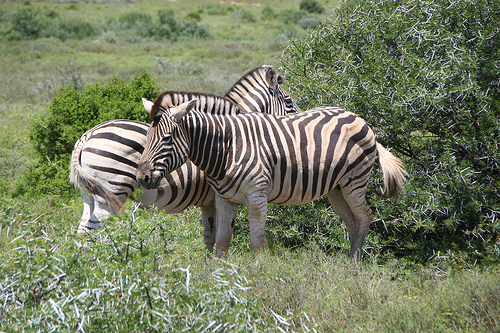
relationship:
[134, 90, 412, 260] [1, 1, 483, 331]
zebra grazing in a field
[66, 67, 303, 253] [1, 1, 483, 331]
zebra grazing in a field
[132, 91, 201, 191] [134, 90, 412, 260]
head of a zebra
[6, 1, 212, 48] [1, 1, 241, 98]
bushes in grass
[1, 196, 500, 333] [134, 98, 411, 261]
grass under zebra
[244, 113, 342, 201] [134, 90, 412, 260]
stripes on zebra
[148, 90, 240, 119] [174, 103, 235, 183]
hair on neck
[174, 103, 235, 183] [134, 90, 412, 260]
neck of zebra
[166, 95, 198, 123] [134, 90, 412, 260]
ear of zebra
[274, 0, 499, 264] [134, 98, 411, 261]
bush behind zebra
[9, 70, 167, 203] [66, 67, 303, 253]
bush behind zebra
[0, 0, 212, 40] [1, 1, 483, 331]
bushes in field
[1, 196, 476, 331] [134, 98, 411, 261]
grass under zebra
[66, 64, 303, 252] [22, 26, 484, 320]
zebra in grass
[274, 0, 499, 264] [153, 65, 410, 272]
bush behind zebra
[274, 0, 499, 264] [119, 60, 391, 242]
bush next to zebra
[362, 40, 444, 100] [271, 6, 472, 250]
leaves on tree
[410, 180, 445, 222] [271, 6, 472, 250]
leaves on tree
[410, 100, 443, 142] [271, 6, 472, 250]
leaves on tree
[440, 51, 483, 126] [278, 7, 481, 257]
leaves on tree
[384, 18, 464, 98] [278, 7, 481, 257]
leaves on tree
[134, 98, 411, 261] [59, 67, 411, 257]
zebra facing away from each other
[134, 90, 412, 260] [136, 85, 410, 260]
zebra facing towards left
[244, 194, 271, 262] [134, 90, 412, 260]
leg of zebra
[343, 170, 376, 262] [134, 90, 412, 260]
leg of zebra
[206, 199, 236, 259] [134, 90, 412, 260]
leg of zebra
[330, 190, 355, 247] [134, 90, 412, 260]
leg of zebra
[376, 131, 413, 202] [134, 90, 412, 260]
tail of zebra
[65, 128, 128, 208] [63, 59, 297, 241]
tail of zebra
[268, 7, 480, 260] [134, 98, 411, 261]
bush near zebra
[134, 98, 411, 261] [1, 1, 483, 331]
zebra in a field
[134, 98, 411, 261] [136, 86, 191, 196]
zebra standing front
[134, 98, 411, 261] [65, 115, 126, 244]
zebra standing back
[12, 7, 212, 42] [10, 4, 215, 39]
line of bushes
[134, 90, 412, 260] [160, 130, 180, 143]
zebra with eyes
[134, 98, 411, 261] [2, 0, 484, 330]
zebra in plain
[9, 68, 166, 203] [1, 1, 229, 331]
bush in ground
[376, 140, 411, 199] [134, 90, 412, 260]
tail of zebra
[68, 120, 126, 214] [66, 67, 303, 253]
tail of zebra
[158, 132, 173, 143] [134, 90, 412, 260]
eye of zebra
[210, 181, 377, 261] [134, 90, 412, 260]
legs of zebra